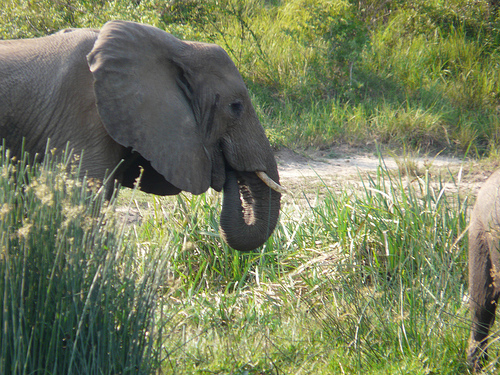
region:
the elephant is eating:
[17, 31, 378, 306]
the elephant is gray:
[28, 22, 385, 334]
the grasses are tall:
[61, 185, 357, 373]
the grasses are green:
[103, 170, 426, 350]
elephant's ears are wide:
[56, 5, 283, 262]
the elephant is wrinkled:
[181, 54, 307, 303]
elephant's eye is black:
[203, 75, 267, 153]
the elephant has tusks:
[64, 36, 337, 301]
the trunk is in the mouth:
[205, 138, 335, 273]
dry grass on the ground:
[286, 246, 374, 306]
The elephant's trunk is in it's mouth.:
[185, 167, 292, 227]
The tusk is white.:
[256, 167, 303, 202]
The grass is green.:
[295, 308, 374, 338]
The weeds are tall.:
[36, 223, 121, 319]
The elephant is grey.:
[41, 89, 89, 128]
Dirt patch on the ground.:
[305, 144, 382, 173]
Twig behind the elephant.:
[177, 0, 294, 77]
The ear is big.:
[106, 33, 226, 128]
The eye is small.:
[222, 93, 259, 119]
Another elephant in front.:
[466, 210, 499, 266]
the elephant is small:
[453, 180, 498, 355]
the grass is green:
[326, 215, 446, 374]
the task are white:
[249, 170, 295, 210]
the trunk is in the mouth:
[69, 0, 266, 236]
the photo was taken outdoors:
[4, 16, 496, 358]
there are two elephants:
[9, 29, 499, 306]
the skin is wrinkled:
[19, 69, 110, 146]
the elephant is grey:
[23, 45, 283, 212]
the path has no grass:
[326, 148, 448, 193]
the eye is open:
[210, 79, 277, 159]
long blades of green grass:
[48, 275, 174, 320]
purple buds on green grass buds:
[33, 144, 133, 231]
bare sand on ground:
[313, 148, 391, 180]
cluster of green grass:
[290, 14, 431, 107]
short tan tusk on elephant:
[257, 156, 294, 211]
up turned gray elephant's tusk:
[209, 157, 321, 269]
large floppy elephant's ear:
[85, 17, 226, 243]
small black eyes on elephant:
[217, 88, 259, 140]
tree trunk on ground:
[370, 8, 495, 57]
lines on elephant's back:
[17, 83, 106, 160]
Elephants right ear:
[80, 12, 214, 192]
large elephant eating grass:
[2, 17, 291, 259]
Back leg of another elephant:
[435, 136, 497, 357]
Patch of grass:
[3, 136, 178, 371]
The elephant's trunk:
[222, 162, 287, 255]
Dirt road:
[274, 125, 499, 215]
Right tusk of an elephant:
[251, 165, 291, 201]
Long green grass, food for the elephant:
[131, 205, 464, 371]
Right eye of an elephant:
[220, 90, 251, 120]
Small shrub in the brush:
[286, 4, 370, 98]